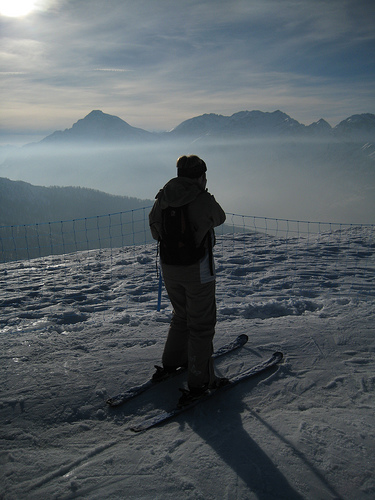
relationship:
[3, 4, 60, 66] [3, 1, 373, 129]
sun in sky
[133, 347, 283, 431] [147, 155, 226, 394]
ski on a person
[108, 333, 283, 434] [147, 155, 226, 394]
ski on a person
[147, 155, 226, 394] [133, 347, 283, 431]
person wearing a ski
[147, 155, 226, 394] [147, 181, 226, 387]
person wearing snow suit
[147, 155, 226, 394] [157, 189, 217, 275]
person has a backpack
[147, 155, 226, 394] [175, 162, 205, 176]
person wearing a head band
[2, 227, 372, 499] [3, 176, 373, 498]
snow on a hill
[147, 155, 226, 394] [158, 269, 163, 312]
person holding ski pole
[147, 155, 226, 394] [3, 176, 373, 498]
person on a hill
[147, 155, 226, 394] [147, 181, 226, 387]
person wearing a snow suit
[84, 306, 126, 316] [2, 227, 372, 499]
tracks in snow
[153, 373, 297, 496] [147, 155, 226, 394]
shadow cast by person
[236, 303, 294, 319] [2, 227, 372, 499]
pit in snow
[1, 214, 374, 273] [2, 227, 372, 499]
fence in snow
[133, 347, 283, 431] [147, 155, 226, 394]
ski belongs to person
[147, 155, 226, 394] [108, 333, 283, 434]
person has a ski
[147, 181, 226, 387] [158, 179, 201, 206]
snow suit has a hood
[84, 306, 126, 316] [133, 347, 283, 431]
tracks from ski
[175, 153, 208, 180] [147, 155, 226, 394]
hat on person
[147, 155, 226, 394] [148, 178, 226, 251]
person wearing a coat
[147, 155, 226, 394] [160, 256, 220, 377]
person wearing pants